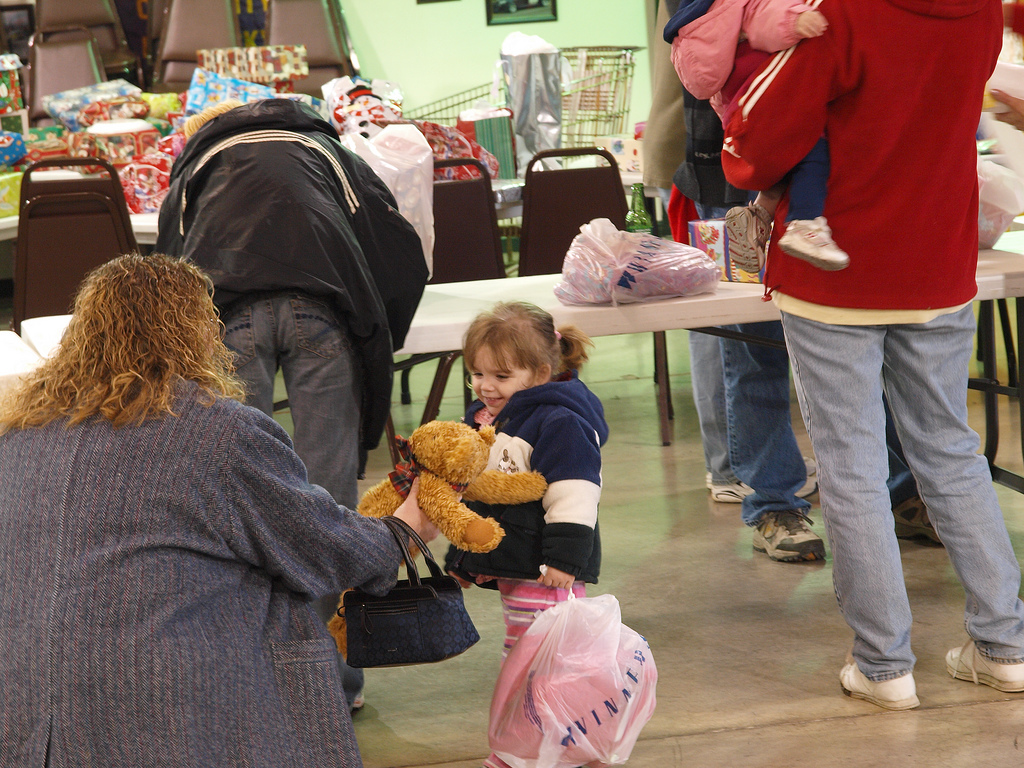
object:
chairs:
[27, 4, 355, 134]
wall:
[325, 0, 650, 165]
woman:
[0, 254, 429, 768]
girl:
[441, 305, 658, 767]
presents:
[0, 56, 499, 221]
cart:
[499, 30, 568, 171]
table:
[0, 95, 484, 213]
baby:
[663, 0, 852, 272]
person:
[718, 1, 1024, 706]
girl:
[443, 301, 660, 768]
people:
[0, 4, 1022, 768]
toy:
[356, 421, 547, 555]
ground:
[5, 298, 1024, 764]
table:
[5, 254, 783, 422]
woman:
[0, 250, 441, 764]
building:
[2, 0, 1021, 767]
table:
[3, 152, 534, 268]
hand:
[389, 479, 446, 553]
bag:
[485, 562, 660, 765]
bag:
[555, 217, 722, 308]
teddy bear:
[354, 418, 541, 557]